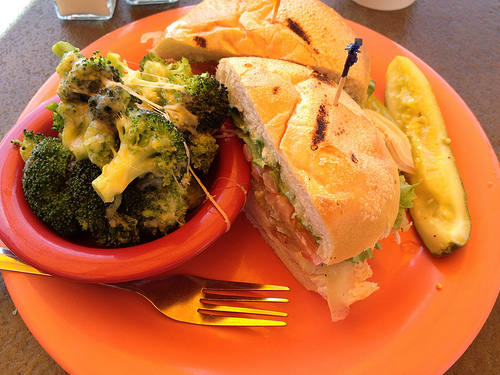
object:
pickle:
[382, 57, 471, 260]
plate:
[0, 5, 499, 374]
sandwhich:
[210, 56, 415, 324]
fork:
[0, 248, 291, 331]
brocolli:
[90, 107, 192, 204]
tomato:
[284, 223, 322, 266]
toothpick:
[334, 38, 364, 108]